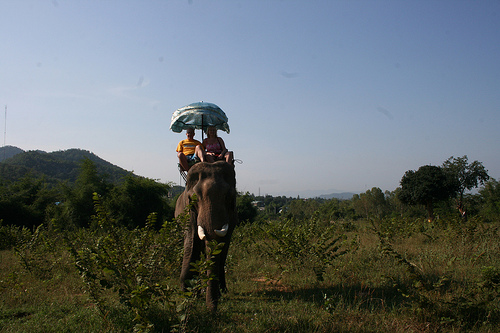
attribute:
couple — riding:
[173, 120, 242, 165]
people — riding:
[168, 126, 241, 174]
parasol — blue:
[166, 96, 236, 134]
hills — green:
[2, 147, 104, 224]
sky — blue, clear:
[48, 10, 495, 102]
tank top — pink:
[207, 142, 228, 160]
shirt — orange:
[178, 142, 203, 163]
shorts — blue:
[185, 160, 195, 176]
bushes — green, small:
[48, 220, 188, 316]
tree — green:
[394, 158, 459, 210]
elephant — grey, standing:
[166, 177, 247, 311]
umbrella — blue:
[165, 96, 234, 139]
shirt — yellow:
[179, 152, 203, 161]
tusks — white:
[188, 210, 233, 244]